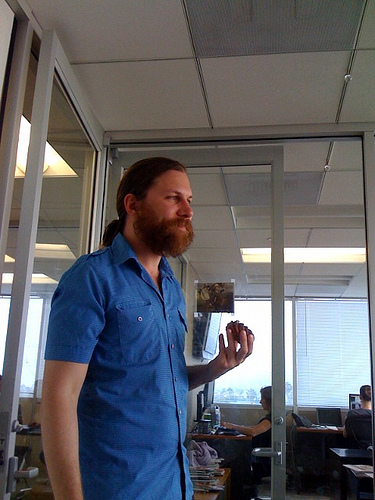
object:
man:
[24, 141, 260, 500]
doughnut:
[226, 318, 256, 345]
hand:
[209, 316, 256, 388]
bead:
[134, 203, 195, 262]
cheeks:
[150, 198, 169, 221]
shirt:
[40, 230, 203, 500]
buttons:
[177, 404, 186, 417]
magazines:
[191, 467, 215, 474]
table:
[193, 462, 238, 500]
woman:
[222, 382, 285, 482]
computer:
[198, 371, 219, 422]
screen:
[268, 134, 372, 500]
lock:
[272, 411, 286, 430]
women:
[222, 384, 283, 490]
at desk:
[193, 422, 255, 447]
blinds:
[291, 290, 374, 415]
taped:
[230, 277, 236, 285]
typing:
[221, 411, 238, 433]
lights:
[237, 239, 370, 275]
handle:
[248, 441, 288, 467]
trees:
[221, 385, 239, 403]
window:
[216, 299, 374, 405]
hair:
[132, 167, 146, 183]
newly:
[97, 156, 280, 500]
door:
[268, 128, 372, 500]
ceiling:
[0, 0, 374, 292]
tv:
[200, 304, 224, 363]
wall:
[184, 272, 224, 422]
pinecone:
[190, 420, 206, 437]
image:
[191, 274, 241, 320]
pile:
[188, 458, 223, 494]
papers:
[190, 471, 215, 478]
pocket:
[113, 293, 164, 369]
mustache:
[165, 217, 198, 228]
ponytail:
[98, 211, 127, 249]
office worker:
[341, 380, 375, 452]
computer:
[346, 390, 368, 415]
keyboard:
[213, 421, 244, 438]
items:
[184, 434, 221, 471]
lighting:
[0, 110, 86, 188]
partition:
[294, 432, 344, 480]